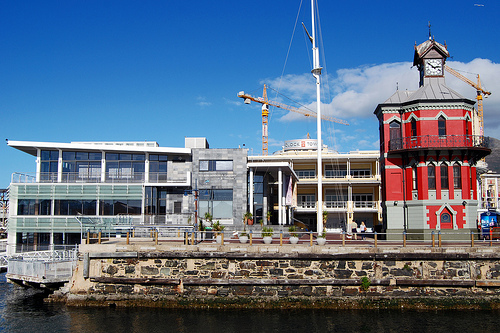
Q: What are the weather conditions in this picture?
A: It is clear.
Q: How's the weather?
A: It is clear.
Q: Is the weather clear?
A: Yes, it is clear.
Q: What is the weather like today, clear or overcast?
A: It is clear.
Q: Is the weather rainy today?
A: No, it is clear.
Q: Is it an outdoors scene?
A: Yes, it is outdoors.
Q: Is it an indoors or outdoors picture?
A: It is outdoors.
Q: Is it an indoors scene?
A: No, it is outdoors.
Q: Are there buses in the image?
A: No, there are no buses.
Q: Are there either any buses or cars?
A: No, there are no buses or cars.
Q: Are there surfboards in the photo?
A: No, there are no surfboards.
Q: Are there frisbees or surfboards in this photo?
A: No, there are no surfboards or frisbees.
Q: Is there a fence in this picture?
A: Yes, there is a fence.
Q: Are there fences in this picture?
A: Yes, there is a fence.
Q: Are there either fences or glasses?
A: Yes, there is a fence.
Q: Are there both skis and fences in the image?
A: No, there is a fence but no skis.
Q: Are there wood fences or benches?
A: Yes, there is a wood fence.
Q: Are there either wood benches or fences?
A: Yes, there is a wood fence.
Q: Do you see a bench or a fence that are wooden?
A: Yes, the fence is wooden.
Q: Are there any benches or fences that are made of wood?
A: Yes, the fence is made of wood.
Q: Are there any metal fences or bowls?
A: Yes, there is a metal fence.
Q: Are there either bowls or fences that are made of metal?
A: Yes, the fence is made of metal.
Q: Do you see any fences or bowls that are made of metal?
A: Yes, the fence is made of metal.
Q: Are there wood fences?
A: Yes, there is a wood fence.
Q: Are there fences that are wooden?
A: Yes, there is a fence that is wooden.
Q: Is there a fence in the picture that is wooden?
A: Yes, there is a fence that is wooden.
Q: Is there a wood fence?
A: Yes, there is a fence that is made of wood.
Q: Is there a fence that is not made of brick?
A: Yes, there is a fence that is made of wood.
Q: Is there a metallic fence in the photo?
A: Yes, there is a metal fence.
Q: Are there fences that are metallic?
A: Yes, there is a fence that is metallic.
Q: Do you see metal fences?
A: Yes, there is a fence that is made of metal.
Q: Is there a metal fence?
A: Yes, there is a fence that is made of metal.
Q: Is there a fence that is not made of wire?
A: Yes, there is a fence that is made of metal.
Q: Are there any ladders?
A: No, there are no ladders.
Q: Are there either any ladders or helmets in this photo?
A: No, there are no ladders or helmets.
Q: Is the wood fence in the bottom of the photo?
A: Yes, the fence is in the bottom of the image.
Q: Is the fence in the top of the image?
A: No, the fence is in the bottom of the image.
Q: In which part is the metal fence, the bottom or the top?
A: The fence is in the bottom of the image.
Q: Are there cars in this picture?
A: No, there are no cars.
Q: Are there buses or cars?
A: No, there are no cars or buses.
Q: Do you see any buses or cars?
A: No, there are no cars or buses.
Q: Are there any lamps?
A: No, there are no lamps.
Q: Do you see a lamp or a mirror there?
A: No, there are no lamps or mirrors.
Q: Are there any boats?
A: Yes, there is a boat.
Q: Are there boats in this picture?
A: Yes, there is a boat.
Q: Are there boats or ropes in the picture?
A: Yes, there is a boat.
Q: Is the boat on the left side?
A: Yes, the boat is on the left of the image.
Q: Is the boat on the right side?
A: No, the boat is on the left of the image.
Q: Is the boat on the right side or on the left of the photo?
A: The boat is on the left of the image.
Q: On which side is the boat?
A: The boat is on the left of the image.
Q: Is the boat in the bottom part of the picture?
A: Yes, the boat is in the bottom of the image.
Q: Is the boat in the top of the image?
A: No, the boat is in the bottom of the image.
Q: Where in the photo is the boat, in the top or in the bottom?
A: The boat is in the bottom of the image.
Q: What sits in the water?
A: The boat sits in the water.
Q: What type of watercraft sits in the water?
A: The watercraft is a boat.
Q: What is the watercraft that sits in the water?
A: The watercraft is a boat.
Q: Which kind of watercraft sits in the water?
A: The watercraft is a boat.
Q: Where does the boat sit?
A: The boat sits in the water.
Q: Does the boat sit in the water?
A: Yes, the boat sits in the water.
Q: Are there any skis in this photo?
A: No, there are no skis.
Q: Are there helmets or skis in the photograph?
A: No, there are no skis or helmets.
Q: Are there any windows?
A: Yes, there is a window.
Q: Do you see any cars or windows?
A: Yes, there is a window.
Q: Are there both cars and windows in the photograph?
A: No, there is a window but no cars.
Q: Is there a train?
A: No, there are no trains.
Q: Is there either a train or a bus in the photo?
A: No, there are no trains or buses.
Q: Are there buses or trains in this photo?
A: No, there are no trains or buses.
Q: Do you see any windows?
A: Yes, there is a window.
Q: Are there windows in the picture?
A: Yes, there is a window.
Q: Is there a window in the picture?
A: Yes, there is a window.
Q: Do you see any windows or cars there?
A: Yes, there is a window.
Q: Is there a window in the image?
A: Yes, there is a window.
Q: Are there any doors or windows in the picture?
A: Yes, there is a window.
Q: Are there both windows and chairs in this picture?
A: No, there is a window but no chairs.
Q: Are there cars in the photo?
A: No, there are no cars.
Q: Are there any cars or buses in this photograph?
A: No, there are no cars or buses.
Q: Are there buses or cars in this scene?
A: No, there are no cars or buses.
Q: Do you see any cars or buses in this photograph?
A: No, there are no cars or buses.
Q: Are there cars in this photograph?
A: No, there are no cars.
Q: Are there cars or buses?
A: No, there are no cars or buses.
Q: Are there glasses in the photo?
A: No, there are no glasses.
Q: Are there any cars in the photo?
A: No, there are no cars.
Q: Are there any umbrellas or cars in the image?
A: No, there are no cars or umbrellas.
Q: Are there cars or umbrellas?
A: No, there are no cars or umbrellas.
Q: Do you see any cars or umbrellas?
A: No, there are no cars or umbrellas.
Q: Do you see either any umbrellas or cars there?
A: No, there are no cars or umbrellas.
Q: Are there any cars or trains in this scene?
A: No, there are no cars or trains.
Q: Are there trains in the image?
A: No, there are no trains.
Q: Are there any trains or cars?
A: No, there are no trains or cars.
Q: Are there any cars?
A: No, there are no cars.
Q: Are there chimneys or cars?
A: No, there are no cars or chimneys.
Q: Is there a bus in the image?
A: No, there are no buses.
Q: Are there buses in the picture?
A: No, there are no buses.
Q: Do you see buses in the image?
A: No, there are no buses.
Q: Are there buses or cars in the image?
A: No, there are no buses or cars.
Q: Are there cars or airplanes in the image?
A: No, there are no cars or airplanes.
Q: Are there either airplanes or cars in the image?
A: No, there are no cars or airplanes.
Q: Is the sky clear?
A: Yes, the sky is clear.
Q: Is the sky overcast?
A: No, the sky is clear.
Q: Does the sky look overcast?
A: No, the sky is clear.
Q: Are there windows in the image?
A: Yes, there is a window.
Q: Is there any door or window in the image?
A: Yes, there is a window.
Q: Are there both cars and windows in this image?
A: No, there is a window but no cars.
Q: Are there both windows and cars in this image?
A: No, there is a window but no cars.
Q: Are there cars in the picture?
A: No, there are no cars.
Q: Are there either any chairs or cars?
A: No, there are no cars or chairs.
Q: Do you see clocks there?
A: Yes, there is a clock.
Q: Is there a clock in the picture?
A: Yes, there is a clock.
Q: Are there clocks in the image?
A: Yes, there is a clock.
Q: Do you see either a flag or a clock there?
A: Yes, there is a clock.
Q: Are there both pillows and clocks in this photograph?
A: No, there is a clock but no pillows.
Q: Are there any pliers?
A: No, there are no pliers.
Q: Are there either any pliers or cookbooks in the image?
A: No, there are no pliers or cookbooks.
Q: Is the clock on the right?
A: Yes, the clock is on the right of the image.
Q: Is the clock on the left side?
A: No, the clock is on the right of the image.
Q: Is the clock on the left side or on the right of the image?
A: The clock is on the right of the image.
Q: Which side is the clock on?
A: The clock is on the right of the image.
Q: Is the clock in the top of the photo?
A: Yes, the clock is in the top of the image.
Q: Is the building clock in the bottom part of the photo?
A: No, the clock is in the top of the image.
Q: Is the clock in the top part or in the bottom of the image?
A: The clock is in the top of the image.